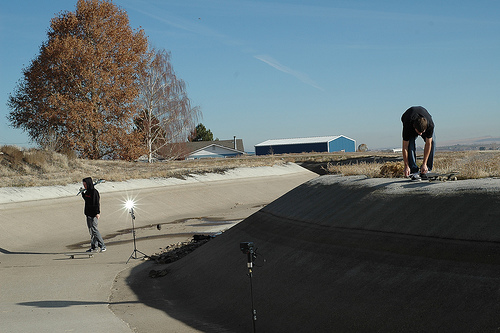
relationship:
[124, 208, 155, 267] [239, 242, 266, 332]
part of camera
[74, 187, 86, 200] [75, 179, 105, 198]
part of a board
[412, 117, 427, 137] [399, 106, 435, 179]
head of man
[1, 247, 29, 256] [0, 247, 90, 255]
part of shadow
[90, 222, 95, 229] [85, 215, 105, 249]
part of trousers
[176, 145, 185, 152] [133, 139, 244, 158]
part of a roof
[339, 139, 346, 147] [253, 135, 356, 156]
portion of building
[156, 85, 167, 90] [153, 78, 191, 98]
part of a branch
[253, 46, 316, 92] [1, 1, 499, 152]
clouds are in sky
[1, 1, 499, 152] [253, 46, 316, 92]
sky has clouds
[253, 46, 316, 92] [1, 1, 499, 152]
clouds in a sky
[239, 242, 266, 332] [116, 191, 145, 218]
camera reflects light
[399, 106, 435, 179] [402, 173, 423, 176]
person holding onto rod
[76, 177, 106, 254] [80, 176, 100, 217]
skateboarder wearing hoodie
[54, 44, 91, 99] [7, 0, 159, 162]
leaves covering a tree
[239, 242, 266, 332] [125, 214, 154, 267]
camera on tripod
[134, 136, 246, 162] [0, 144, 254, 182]
house behind hill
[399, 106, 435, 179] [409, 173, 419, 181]
person tying shoe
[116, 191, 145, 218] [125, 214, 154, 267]
light on tripod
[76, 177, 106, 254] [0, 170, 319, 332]
skateboarder on asphalt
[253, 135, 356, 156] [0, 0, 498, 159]
building in background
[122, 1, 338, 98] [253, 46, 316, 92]
line of clouds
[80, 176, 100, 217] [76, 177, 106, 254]
hoodie on skateboarder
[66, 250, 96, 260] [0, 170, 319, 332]
skateboard on asphalt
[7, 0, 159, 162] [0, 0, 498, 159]
tree in background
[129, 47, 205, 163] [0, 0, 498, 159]
tree in background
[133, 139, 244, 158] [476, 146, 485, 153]
roof of house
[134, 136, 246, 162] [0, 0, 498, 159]
house in background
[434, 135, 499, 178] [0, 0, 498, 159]
hills in background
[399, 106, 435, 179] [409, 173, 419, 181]
man tying shoe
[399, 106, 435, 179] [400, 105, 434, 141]
man wearing shirt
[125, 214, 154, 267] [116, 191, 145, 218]
tripod with a light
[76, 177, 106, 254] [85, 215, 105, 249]
skateboarder wearing trousers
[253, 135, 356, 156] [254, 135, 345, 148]
building with roof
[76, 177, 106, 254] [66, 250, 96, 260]
skateboarder next to skateboard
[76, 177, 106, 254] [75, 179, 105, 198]
skateboarder carrying skateboard